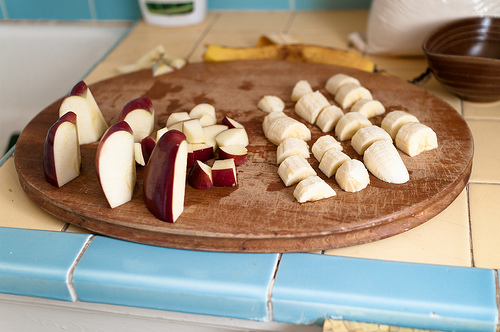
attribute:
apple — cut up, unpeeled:
[43, 111, 80, 187]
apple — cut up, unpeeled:
[59, 80, 109, 144]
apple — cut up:
[95, 122, 138, 208]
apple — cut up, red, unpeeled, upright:
[143, 130, 188, 223]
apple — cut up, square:
[212, 159, 237, 185]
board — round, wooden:
[15, 60, 474, 253]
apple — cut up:
[220, 146, 247, 166]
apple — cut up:
[185, 119, 205, 144]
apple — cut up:
[167, 110, 190, 126]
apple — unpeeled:
[187, 160, 212, 188]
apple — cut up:
[190, 104, 215, 116]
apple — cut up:
[133, 142, 146, 166]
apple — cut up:
[191, 143, 213, 161]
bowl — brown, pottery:
[423, 16, 500, 102]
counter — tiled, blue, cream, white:
[0, 10, 499, 332]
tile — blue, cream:
[1, 227, 92, 303]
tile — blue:
[71, 235, 279, 323]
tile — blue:
[271, 252, 497, 332]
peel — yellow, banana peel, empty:
[203, 35, 375, 71]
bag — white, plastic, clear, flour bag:
[349, 0, 499, 58]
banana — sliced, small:
[293, 178, 335, 203]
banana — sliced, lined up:
[278, 157, 316, 186]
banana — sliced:
[351, 127, 393, 155]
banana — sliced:
[396, 124, 438, 157]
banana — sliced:
[312, 136, 342, 161]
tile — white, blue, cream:
[468, 181, 499, 270]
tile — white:
[322, 183, 474, 269]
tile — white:
[464, 119, 499, 183]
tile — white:
[1, 155, 66, 232]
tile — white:
[211, 11, 291, 33]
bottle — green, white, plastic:
[137, 0, 205, 26]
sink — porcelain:
[0, 21, 132, 166]